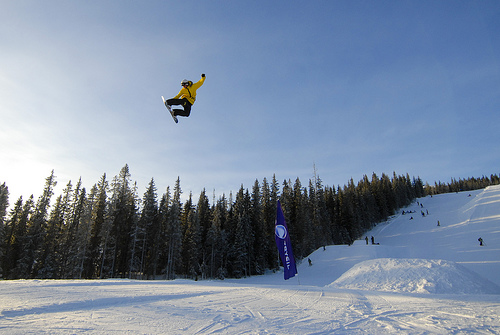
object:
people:
[305, 257, 314, 266]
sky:
[0, 0, 499, 220]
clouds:
[0, 0, 499, 212]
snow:
[0, 278, 499, 334]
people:
[476, 235, 484, 247]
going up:
[158, 70, 210, 126]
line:
[241, 304, 255, 320]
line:
[342, 308, 400, 327]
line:
[204, 321, 232, 335]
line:
[435, 309, 474, 319]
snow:
[0, 185, 500, 334]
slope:
[242, 184, 500, 298]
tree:
[0, 164, 499, 280]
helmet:
[178, 78, 196, 86]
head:
[179, 78, 195, 87]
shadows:
[41, 185, 500, 305]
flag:
[273, 195, 301, 281]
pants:
[165, 96, 192, 118]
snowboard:
[160, 94, 182, 125]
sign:
[274, 223, 288, 240]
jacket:
[170, 74, 204, 106]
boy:
[164, 74, 208, 118]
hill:
[273, 185, 499, 293]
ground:
[0, 270, 499, 334]